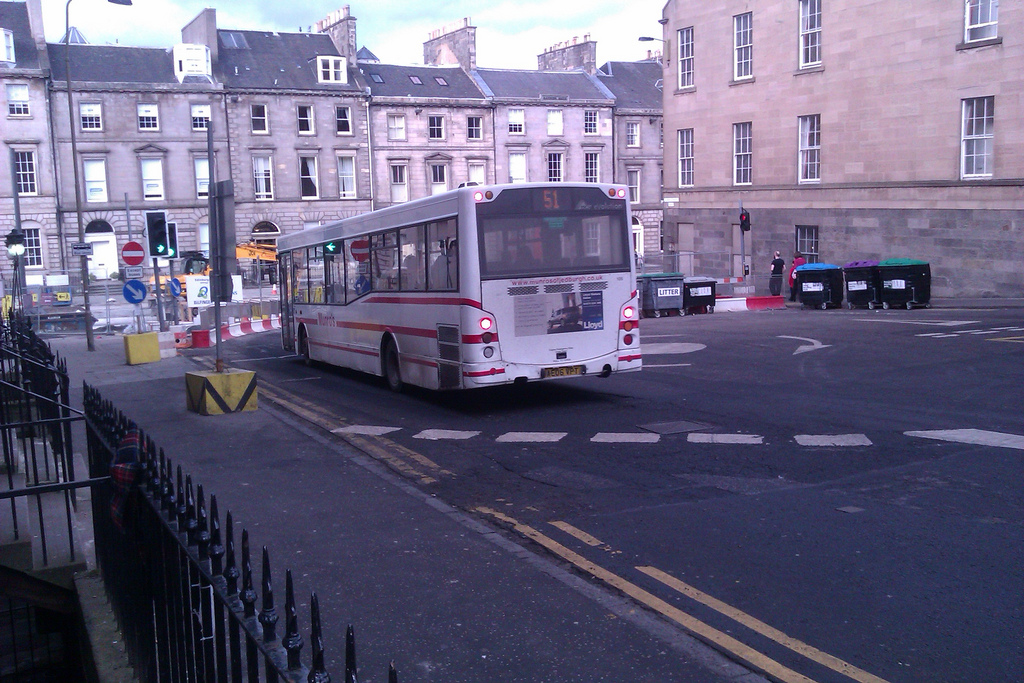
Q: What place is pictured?
A: It is a street.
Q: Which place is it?
A: It is a street.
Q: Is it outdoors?
A: Yes, it is outdoors.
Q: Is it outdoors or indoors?
A: It is outdoors.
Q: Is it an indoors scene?
A: No, it is outdoors.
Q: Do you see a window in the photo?
A: Yes, there is a window.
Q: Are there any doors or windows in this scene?
A: Yes, there is a window.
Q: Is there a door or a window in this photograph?
A: Yes, there is a window.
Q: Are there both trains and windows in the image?
A: No, there is a window but no trains.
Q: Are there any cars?
A: No, there are no cars.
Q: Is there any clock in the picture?
A: No, there are no clocks.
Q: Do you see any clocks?
A: No, there are no clocks.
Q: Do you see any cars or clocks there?
A: No, there are no clocks or cars.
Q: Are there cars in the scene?
A: No, there are no cars.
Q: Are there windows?
A: Yes, there is a window.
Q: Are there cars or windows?
A: Yes, there is a window.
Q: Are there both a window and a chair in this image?
A: No, there is a window but no chairs.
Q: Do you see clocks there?
A: No, there are no clocks.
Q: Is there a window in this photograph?
A: Yes, there is a window.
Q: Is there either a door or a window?
A: Yes, there is a window.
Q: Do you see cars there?
A: No, there are no cars.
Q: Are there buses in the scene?
A: Yes, there is a bus.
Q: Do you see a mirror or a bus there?
A: Yes, there is a bus.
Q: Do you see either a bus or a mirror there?
A: Yes, there is a bus.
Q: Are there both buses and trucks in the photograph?
A: No, there is a bus but no trucks.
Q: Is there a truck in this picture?
A: No, there are no trucks.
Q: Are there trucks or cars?
A: No, there are no trucks or cars.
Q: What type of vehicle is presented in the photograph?
A: The vehicle is a bus.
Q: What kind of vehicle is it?
A: The vehicle is a bus.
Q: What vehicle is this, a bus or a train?
A: This is a bus.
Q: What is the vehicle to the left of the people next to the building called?
A: The vehicle is a bus.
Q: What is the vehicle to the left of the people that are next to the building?
A: The vehicle is a bus.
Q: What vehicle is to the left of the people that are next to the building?
A: The vehicle is a bus.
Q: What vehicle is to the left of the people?
A: The vehicle is a bus.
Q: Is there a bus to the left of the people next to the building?
A: Yes, there is a bus to the left of the people.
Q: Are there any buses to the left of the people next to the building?
A: Yes, there is a bus to the left of the people.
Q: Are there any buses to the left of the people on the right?
A: Yes, there is a bus to the left of the people.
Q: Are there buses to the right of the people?
A: No, the bus is to the left of the people.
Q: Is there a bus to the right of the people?
A: No, the bus is to the left of the people.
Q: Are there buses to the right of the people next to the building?
A: No, the bus is to the left of the people.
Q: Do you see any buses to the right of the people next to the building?
A: No, the bus is to the left of the people.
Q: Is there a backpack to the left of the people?
A: No, there is a bus to the left of the people.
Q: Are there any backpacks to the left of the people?
A: No, there is a bus to the left of the people.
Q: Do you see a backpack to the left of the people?
A: No, there is a bus to the left of the people.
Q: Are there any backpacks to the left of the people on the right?
A: No, there is a bus to the left of the people.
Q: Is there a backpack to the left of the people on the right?
A: No, there is a bus to the left of the people.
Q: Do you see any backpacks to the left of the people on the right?
A: No, there is a bus to the left of the people.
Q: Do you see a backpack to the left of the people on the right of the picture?
A: No, there is a bus to the left of the people.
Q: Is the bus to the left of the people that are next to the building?
A: Yes, the bus is to the left of the people.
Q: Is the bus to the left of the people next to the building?
A: Yes, the bus is to the left of the people.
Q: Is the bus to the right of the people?
A: No, the bus is to the left of the people.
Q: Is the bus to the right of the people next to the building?
A: No, the bus is to the left of the people.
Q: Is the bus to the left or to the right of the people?
A: The bus is to the left of the people.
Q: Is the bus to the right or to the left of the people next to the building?
A: The bus is to the left of the people.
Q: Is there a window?
A: Yes, there is a window.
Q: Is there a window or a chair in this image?
A: Yes, there is a window.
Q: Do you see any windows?
A: Yes, there is a window.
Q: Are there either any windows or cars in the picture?
A: Yes, there is a window.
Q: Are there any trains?
A: No, there are no trains.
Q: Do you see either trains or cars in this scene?
A: No, there are no trains or cars.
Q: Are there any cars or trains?
A: No, there are no trains or cars.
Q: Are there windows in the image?
A: Yes, there is a window.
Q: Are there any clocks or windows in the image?
A: Yes, there is a window.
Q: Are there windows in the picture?
A: Yes, there is a window.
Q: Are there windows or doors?
A: Yes, there is a window.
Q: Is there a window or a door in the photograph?
A: Yes, there is a window.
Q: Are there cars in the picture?
A: No, there are no cars.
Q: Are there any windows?
A: Yes, there is a window.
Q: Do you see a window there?
A: Yes, there is a window.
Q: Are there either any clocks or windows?
A: Yes, there is a window.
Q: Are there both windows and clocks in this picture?
A: No, there is a window but no clocks.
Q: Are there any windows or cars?
A: Yes, there is a window.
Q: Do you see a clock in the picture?
A: No, there are no clocks.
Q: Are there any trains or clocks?
A: No, there are no clocks or trains.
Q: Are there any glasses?
A: No, there are no glasses.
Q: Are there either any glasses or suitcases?
A: No, there are no glasses or suitcases.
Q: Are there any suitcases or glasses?
A: No, there are no glasses or suitcases.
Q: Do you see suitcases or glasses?
A: No, there are no glasses or suitcases.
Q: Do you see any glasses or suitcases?
A: No, there are no glasses or suitcases.